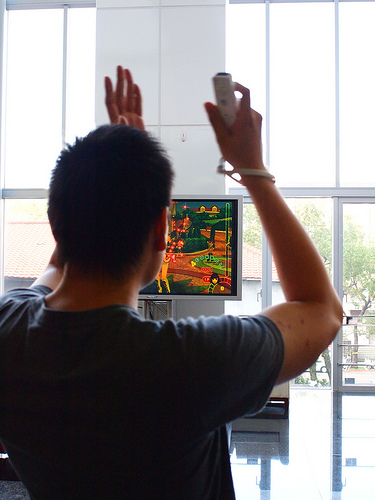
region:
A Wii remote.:
[192, 66, 291, 182]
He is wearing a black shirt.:
[0, 271, 285, 497]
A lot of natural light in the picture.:
[228, 139, 373, 481]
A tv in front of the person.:
[130, 190, 241, 305]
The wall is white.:
[97, 1, 221, 185]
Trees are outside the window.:
[279, 193, 369, 346]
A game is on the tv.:
[135, 193, 250, 306]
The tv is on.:
[126, 191, 241, 301]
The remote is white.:
[201, 58, 286, 197]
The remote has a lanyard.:
[192, 66, 287, 195]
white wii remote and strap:
[205, 66, 282, 194]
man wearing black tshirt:
[8, 136, 227, 463]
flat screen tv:
[147, 193, 245, 299]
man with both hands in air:
[34, 56, 360, 415]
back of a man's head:
[41, 130, 188, 318]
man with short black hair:
[41, 123, 207, 363]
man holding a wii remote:
[47, 49, 343, 368]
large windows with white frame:
[221, 10, 373, 168]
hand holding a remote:
[204, 65, 284, 198]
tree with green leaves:
[335, 224, 372, 277]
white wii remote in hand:
[195, 69, 252, 112]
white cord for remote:
[210, 150, 283, 185]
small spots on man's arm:
[259, 310, 320, 344]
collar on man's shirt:
[19, 285, 164, 344]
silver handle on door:
[333, 301, 363, 362]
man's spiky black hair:
[47, 122, 174, 203]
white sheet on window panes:
[79, 7, 260, 125]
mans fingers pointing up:
[71, 67, 165, 132]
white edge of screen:
[172, 186, 249, 293]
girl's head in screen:
[196, 264, 223, 292]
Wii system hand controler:
[198, 60, 249, 157]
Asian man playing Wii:
[7, 61, 342, 484]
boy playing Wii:
[7, 51, 342, 491]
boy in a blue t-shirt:
[6, 70, 304, 484]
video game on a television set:
[173, 202, 241, 294]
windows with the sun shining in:
[245, 3, 358, 194]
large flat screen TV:
[147, 198, 242, 294]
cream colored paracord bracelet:
[210, 156, 282, 190]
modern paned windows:
[9, 16, 100, 173]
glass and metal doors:
[300, 191, 369, 402]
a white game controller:
[210, 67, 248, 130]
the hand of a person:
[195, 69, 266, 169]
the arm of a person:
[186, 156, 349, 419]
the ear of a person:
[155, 202, 174, 252]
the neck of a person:
[39, 263, 155, 310]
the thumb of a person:
[200, 98, 228, 139]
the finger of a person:
[229, 76, 252, 115]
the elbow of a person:
[328, 298, 350, 333]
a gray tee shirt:
[0, 283, 288, 498]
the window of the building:
[266, 0, 339, 191]